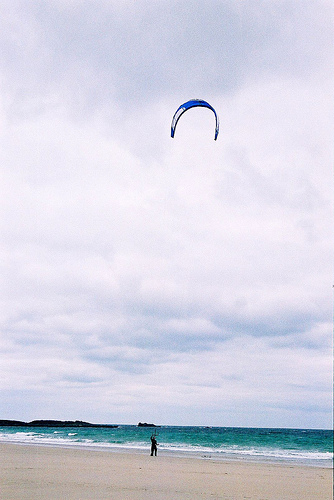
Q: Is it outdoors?
A: Yes, it is outdoors.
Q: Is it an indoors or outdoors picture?
A: It is outdoors.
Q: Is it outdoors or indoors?
A: It is outdoors.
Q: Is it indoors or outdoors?
A: It is outdoors.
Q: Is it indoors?
A: No, it is outdoors.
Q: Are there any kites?
A: Yes, there is a kite.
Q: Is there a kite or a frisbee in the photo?
A: Yes, there is a kite.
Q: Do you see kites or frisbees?
A: Yes, there is a kite.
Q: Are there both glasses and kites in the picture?
A: No, there is a kite but no glasses.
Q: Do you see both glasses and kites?
A: No, there is a kite but no glasses.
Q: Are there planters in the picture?
A: No, there are no planters.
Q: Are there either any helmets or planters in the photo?
A: No, there are no planters or helmets.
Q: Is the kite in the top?
A: Yes, the kite is in the top of the image.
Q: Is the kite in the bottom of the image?
A: No, the kite is in the top of the image.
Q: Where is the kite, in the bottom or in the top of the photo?
A: The kite is in the top of the image.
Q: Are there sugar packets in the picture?
A: No, there are no sugar packets.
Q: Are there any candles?
A: No, there are no candles.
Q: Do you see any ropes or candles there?
A: No, there are no candles or ropes.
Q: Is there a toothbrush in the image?
A: No, there are no toothbrushes.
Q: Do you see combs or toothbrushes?
A: No, there are no toothbrushes or combs.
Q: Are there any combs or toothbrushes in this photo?
A: No, there are no toothbrushes or combs.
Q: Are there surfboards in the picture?
A: No, there are no surfboards.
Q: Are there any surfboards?
A: No, there are no surfboards.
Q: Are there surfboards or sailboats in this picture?
A: No, there are no surfboards or sailboats.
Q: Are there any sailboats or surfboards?
A: No, there are no surfboards or sailboats.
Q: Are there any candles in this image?
A: No, there are no candles.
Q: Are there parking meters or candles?
A: No, there are no candles or parking meters.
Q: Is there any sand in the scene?
A: Yes, there is sand.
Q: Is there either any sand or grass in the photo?
A: Yes, there is sand.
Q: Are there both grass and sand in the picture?
A: No, there is sand but no grass.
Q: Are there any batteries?
A: No, there are no batteries.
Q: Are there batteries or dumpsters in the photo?
A: No, there are no batteries or dumpsters.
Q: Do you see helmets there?
A: No, there are no helmets.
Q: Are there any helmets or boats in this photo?
A: No, there are no helmets or boats.